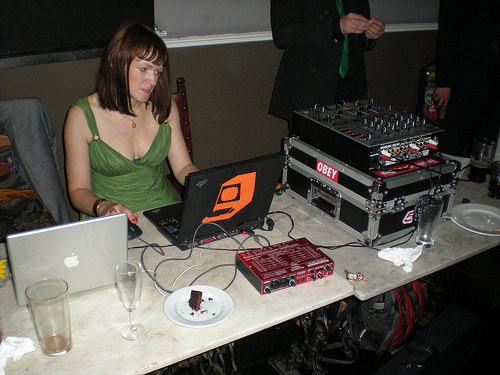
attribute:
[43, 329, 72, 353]
liquid — brown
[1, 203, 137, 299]
laptop — Apple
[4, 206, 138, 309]
laptop — Apple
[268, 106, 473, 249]
case — black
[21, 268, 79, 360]
glass — big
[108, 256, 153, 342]
wine glass — clear, empty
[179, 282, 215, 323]
piece of cake — BROWN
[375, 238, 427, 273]
crumpled napkin — white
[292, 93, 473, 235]
electrical device — red, black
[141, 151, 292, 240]
orange laptop — black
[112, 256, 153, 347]
champagne glass — empty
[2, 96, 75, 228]
mens suit jacket — gray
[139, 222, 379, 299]
multiple wires — together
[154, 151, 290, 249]
laptop — black